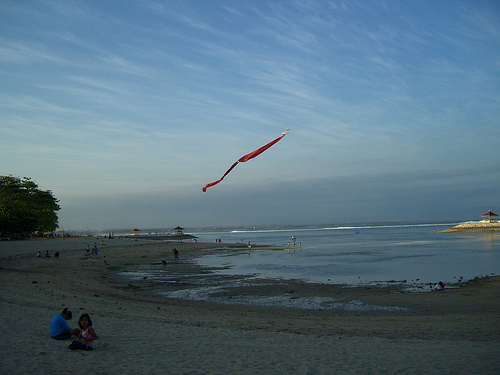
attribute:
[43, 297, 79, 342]
person — sitting, close, small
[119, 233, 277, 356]
beach — sandy, busy, brown, full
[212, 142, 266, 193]
kite — red, big, small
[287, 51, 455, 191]
sky — clear, blue, big, light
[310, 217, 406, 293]
water — blue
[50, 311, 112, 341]
shirt — pink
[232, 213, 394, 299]
ocean — very big